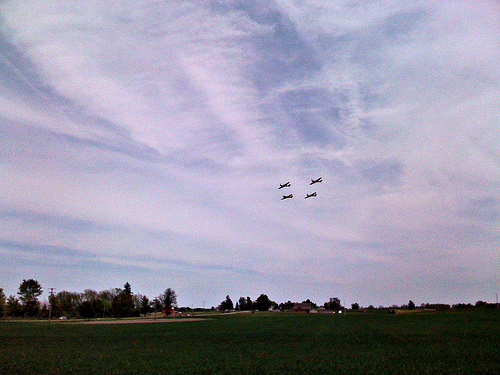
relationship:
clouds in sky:
[0, 0, 499, 302] [0, 0, 499, 308]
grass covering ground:
[358, 324, 429, 361] [0, 305, 499, 372]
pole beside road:
[48, 284, 57, 324] [5, 316, 52, 323]